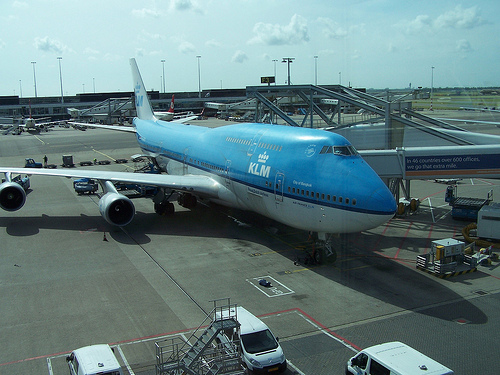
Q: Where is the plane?
A: In an airport.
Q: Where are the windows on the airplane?
A: Along the side.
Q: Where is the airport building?
A: Behind the plane.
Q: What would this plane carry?
A: Passengers.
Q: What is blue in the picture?
A: A plane.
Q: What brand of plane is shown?
A: Klm.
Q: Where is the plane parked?
A: The tarmac.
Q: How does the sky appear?
A: Blue and cloudy.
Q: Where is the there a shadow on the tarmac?
A: Under the plane.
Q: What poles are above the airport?
A: Light poles.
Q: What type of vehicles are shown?
A: Vans.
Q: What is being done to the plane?
A: Maintenance.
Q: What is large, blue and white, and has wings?
A: The airplane.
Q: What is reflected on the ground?
A: The shadow from the plane.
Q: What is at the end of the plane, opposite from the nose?
A: The tail.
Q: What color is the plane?
A: Blue and white.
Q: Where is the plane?
A: On the ground.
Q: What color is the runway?
A: Black.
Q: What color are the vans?
A: White.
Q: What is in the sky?
A: Clouds.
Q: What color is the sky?
A: Blue.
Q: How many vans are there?
A: Two.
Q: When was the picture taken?
A: Daytime.